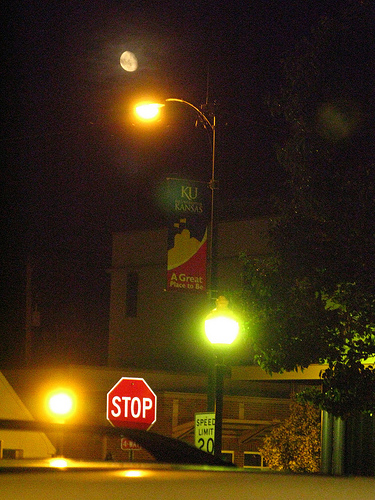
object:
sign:
[106, 376, 158, 432]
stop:
[111, 395, 152, 419]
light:
[126, 93, 172, 132]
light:
[43, 387, 79, 426]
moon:
[118, 49, 138, 75]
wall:
[116, 388, 291, 469]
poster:
[165, 177, 210, 292]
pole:
[209, 117, 216, 418]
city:
[2, 85, 374, 498]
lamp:
[196, 294, 247, 356]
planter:
[320, 401, 371, 478]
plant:
[292, 361, 375, 422]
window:
[125, 267, 138, 319]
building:
[106, 220, 287, 372]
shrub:
[256, 390, 321, 473]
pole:
[213, 361, 223, 456]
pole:
[128, 451, 133, 461]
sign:
[194, 412, 215, 456]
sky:
[8, 9, 375, 304]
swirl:
[168, 236, 207, 273]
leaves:
[263, 268, 278, 296]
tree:
[243, 7, 373, 370]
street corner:
[2, 353, 80, 499]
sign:
[121, 436, 144, 452]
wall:
[116, 266, 250, 370]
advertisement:
[166, 218, 208, 291]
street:
[2, 396, 374, 493]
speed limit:
[198, 436, 214, 453]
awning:
[231, 362, 374, 384]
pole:
[24, 264, 35, 379]